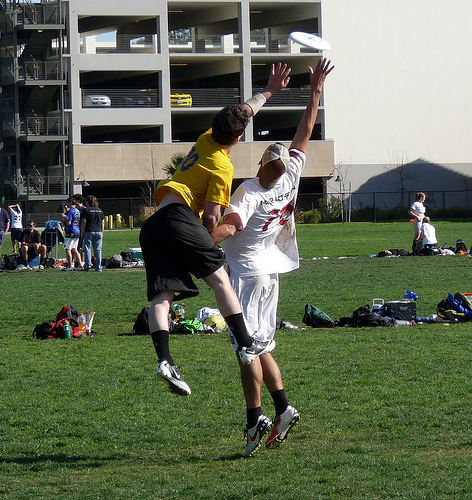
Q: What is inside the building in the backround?
A: Parked cars.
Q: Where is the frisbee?
A: In the air.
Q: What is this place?
A: A park.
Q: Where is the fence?
A: In the backround.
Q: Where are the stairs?
A: Next to the parking garage.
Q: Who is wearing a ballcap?
A: The guy on the right.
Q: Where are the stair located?
A: In the parking garage.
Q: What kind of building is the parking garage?
A: Multistory.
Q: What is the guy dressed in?
A: In white.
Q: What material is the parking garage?
A: Gray concrete.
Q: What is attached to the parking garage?
A: Metal stairs.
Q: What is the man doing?
A: Jumping to catch frisbee.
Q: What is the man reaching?
A: To grab frisbee.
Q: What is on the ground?
A: Bags.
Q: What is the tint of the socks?
A: Black.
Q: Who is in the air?
A: The player in the yellow shirt.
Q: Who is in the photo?
A: People.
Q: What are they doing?
A: Playing.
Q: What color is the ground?
A: Green.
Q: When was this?
A: Daytime.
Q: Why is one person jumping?
A: They are competing.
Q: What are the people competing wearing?
A: Shorts.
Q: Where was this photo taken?
A: In a field.